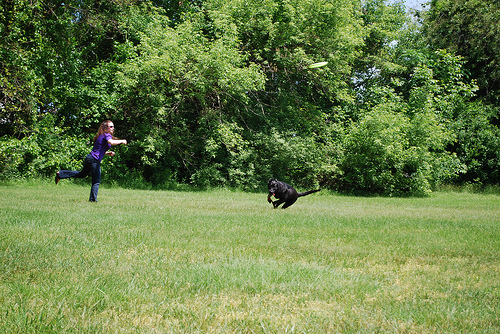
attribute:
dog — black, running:
[267, 176, 323, 215]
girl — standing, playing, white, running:
[52, 112, 130, 207]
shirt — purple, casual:
[90, 134, 111, 163]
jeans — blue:
[53, 153, 104, 205]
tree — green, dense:
[60, 3, 272, 118]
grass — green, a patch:
[126, 210, 214, 256]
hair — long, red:
[92, 119, 107, 142]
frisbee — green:
[306, 57, 334, 69]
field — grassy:
[4, 4, 498, 327]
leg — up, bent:
[46, 158, 94, 185]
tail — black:
[297, 187, 324, 198]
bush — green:
[260, 134, 345, 191]